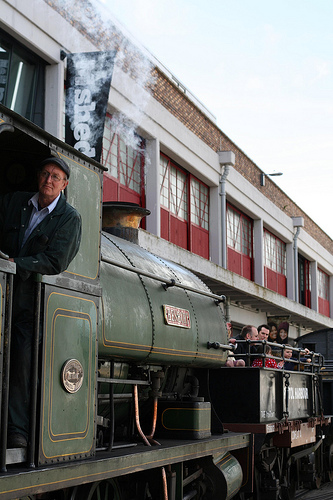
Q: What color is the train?
A: Green.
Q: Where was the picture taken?
A: At a train station.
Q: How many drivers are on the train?
A: 1.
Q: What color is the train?
A: Green.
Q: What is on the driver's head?
A: A hat.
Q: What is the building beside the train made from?
A: Brick.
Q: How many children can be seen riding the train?
A: 2.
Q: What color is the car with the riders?
A: Black.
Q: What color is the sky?
A: Blue.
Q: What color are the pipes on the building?
A: Gray.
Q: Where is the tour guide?
A: Front of the train.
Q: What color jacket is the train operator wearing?
A: Green.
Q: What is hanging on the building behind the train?
A: A banner.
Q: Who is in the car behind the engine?
A: Passengers.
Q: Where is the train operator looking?
A: Forward.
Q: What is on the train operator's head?
A: A hat.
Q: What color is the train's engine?
A: Green.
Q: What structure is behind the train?
A: Building.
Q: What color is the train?
A: Green.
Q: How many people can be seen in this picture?
A: 6.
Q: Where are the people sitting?
A: On a train.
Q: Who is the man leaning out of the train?
A: Engineer/driver.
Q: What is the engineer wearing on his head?
A: A cap.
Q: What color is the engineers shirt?
A: Blue.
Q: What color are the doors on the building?
A: Red.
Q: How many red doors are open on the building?
A: One.